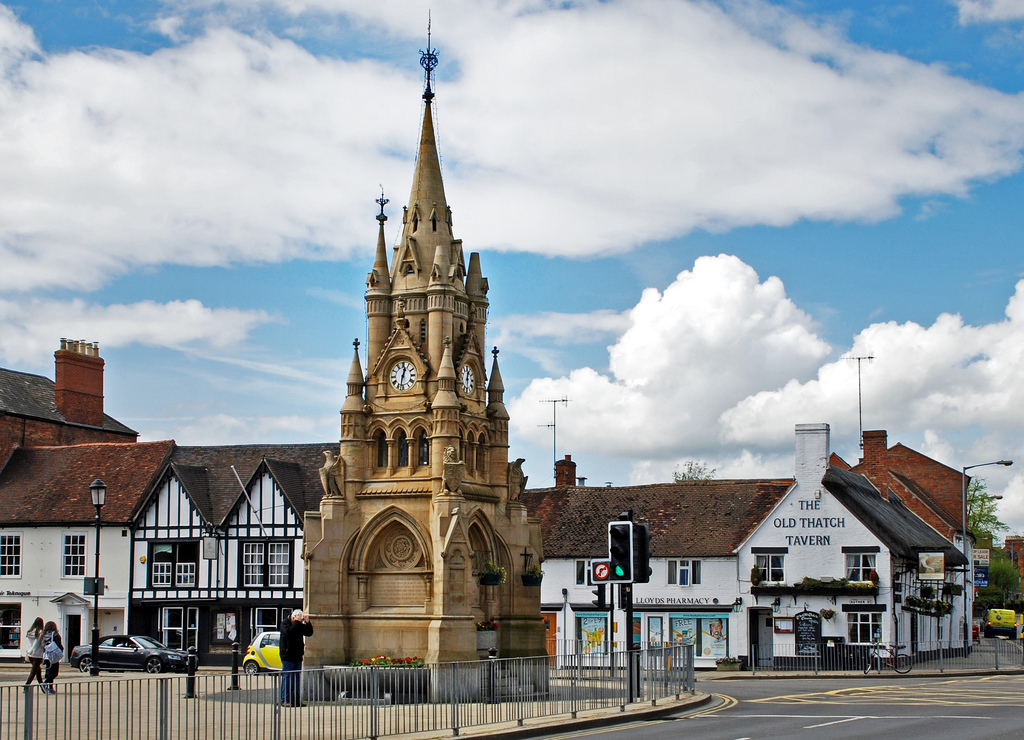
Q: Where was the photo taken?
A: In a church parking lot.